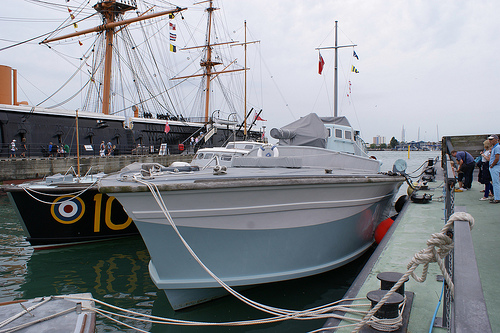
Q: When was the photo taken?
A: Daytime.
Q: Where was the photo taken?
A: A harbor.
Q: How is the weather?
A: Calm.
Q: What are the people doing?
A: Tying the boat.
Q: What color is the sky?
A: Gray.